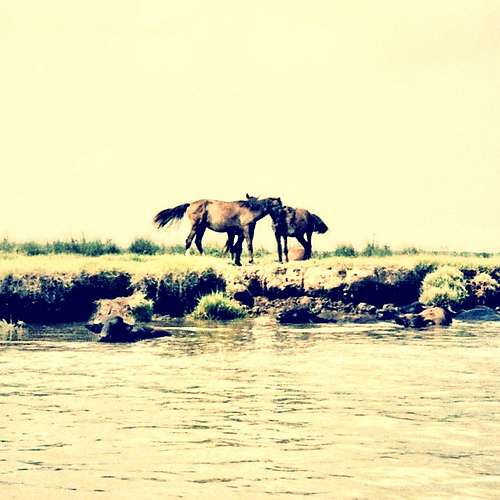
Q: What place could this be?
A: It is a river.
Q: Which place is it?
A: It is a river.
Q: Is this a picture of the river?
A: Yes, it is showing the river.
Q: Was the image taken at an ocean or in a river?
A: It was taken at a river.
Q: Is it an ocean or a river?
A: It is a river.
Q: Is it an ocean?
A: No, it is a river.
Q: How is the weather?
A: It is cloudy.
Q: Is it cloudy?
A: Yes, it is cloudy.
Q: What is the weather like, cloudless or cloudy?
A: It is cloudy.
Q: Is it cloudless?
A: No, it is cloudy.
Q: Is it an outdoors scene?
A: Yes, it is outdoors.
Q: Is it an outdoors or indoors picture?
A: It is outdoors.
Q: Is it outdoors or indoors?
A: It is outdoors.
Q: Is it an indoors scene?
A: No, it is outdoors.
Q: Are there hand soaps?
A: No, there are no hand soaps.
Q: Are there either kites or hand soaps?
A: No, there are no hand soaps or kites.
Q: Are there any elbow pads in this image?
A: No, there are no elbow pads.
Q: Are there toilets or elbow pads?
A: No, there are no elbow pads or toilets.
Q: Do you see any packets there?
A: No, there are no packets.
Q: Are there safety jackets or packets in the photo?
A: No, there are no packets or safety jackets.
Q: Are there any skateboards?
A: No, there are no skateboards.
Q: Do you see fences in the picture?
A: No, there are no fences.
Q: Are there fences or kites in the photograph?
A: No, there are no fences or kites.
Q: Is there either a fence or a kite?
A: No, there are no fences or kites.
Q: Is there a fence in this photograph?
A: No, there are no fences.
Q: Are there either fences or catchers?
A: No, there are no fences or catchers.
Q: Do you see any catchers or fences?
A: No, there are no fences or catchers.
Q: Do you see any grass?
A: Yes, there is grass.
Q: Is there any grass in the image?
A: Yes, there is grass.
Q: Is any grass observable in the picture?
A: Yes, there is grass.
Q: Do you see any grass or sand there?
A: Yes, there is grass.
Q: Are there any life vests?
A: No, there are no life vests.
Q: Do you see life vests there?
A: No, there are no life vests.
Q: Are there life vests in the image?
A: No, there are no life vests.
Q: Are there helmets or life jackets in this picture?
A: No, there are no life jackets or helmets.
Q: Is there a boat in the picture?
A: No, there are no boats.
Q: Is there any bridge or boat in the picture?
A: No, there are no boats or bridges.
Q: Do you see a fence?
A: No, there are no fences.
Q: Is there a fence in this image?
A: No, there are no fences.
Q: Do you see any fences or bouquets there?
A: No, there are no fences or bouquets.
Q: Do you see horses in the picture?
A: Yes, there is a horse.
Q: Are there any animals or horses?
A: Yes, there is a horse.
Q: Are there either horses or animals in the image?
A: Yes, there is a horse.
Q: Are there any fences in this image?
A: No, there are no fences.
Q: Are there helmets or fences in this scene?
A: No, there are no fences or helmets.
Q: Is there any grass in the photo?
A: Yes, there is grass.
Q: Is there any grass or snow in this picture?
A: Yes, there is grass.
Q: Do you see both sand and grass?
A: No, there is grass but no sand.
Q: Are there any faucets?
A: No, there are no faucets.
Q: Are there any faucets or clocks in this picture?
A: No, there are no faucets or clocks.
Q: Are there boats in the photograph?
A: No, there are no boats.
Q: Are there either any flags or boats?
A: No, there are no boats or flags.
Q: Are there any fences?
A: No, there are no fences.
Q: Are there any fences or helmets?
A: No, there are no fences or helmets.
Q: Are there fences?
A: No, there are no fences.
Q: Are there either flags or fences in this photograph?
A: No, there are no fences or flags.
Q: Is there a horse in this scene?
A: Yes, there is a horse.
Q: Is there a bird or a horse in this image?
A: Yes, there is a horse.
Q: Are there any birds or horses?
A: Yes, there is a horse.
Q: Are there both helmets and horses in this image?
A: No, there is a horse but no helmets.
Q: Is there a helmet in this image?
A: No, there are no helmets.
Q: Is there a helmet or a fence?
A: No, there are no helmets or fences.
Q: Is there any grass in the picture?
A: Yes, there is grass.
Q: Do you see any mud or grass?
A: Yes, there is grass.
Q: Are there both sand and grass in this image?
A: No, there is grass but no sand.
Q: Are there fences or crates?
A: No, there are no fences or crates.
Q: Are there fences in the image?
A: No, there are no fences.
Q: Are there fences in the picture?
A: No, there are no fences.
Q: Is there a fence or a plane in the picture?
A: No, there are no fences or airplanes.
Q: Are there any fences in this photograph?
A: No, there are no fences.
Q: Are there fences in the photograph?
A: No, there are no fences.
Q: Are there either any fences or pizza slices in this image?
A: No, there are no fences or pizza slices.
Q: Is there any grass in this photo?
A: Yes, there is grass.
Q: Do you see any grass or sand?
A: Yes, there is grass.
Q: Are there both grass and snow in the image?
A: No, there is grass but no snow.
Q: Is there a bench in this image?
A: No, there are no benches.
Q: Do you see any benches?
A: No, there are no benches.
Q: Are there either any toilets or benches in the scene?
A: No, there are no benches or toilets.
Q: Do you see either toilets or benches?
A: No, there are no benches or toilets.